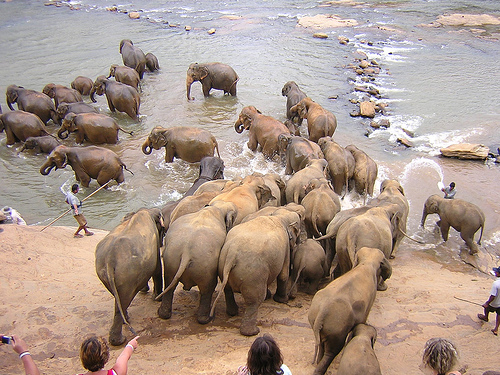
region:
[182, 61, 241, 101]
an elephant in the water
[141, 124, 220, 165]
an elephant in the water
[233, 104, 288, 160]
an elephant in the water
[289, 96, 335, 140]
an elephant in the water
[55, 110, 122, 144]
an elephant in the water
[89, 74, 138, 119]
an elephant in the water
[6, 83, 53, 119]
an elephant in the water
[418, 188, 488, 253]
an elephant in the water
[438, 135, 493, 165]
a rock in the water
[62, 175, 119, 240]
a man herding elephants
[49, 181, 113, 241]
man with stick on bank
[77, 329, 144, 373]
woman pointing toward elephants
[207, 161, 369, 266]
herd of elephants walking toward water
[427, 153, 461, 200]
man throwing bucket of water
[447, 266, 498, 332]
man in shorts holding stick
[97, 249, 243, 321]
tails on back of elephants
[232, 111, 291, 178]
elephants walking in water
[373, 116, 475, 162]
rocks lined up in water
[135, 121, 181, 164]
elephant with curled trunk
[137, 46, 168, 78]
baby elephant in water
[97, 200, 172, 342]
dirt covered elephant walking to water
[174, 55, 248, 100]
elephant in green water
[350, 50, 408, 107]
green water rapid rushing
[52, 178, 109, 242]
man herding elephants through water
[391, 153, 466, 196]
man tossing water with bucket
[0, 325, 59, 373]
person taking picture with camera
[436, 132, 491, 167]
rock not fully submerged under water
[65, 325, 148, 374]
woman pointing at elephants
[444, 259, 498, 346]
man herding elephants with stick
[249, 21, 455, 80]
green colored river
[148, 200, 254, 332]
large elephant trying to get in the water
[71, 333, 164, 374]
lady in red shirt pointing at elephant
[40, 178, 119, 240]
man holding a long stick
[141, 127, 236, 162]
elephant in the water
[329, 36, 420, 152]
cluster of large roks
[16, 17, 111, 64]
large body of water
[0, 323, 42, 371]
person using camera to take picture of elephants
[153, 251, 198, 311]
tail of elphant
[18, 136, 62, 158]
baby elephant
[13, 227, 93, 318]
dirt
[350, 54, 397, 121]
line of rocks in water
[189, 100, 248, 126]
reflection of elephant in toilet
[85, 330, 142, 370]
pointing finger of woman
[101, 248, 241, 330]
tails on backs of elephants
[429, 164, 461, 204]
man throwing water in the air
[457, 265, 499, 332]
man in shorts with a stick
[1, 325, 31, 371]
camera in person's hand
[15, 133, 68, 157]
baby elephant in water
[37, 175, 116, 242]
man with stick above water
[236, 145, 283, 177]
water splashing beside elephant